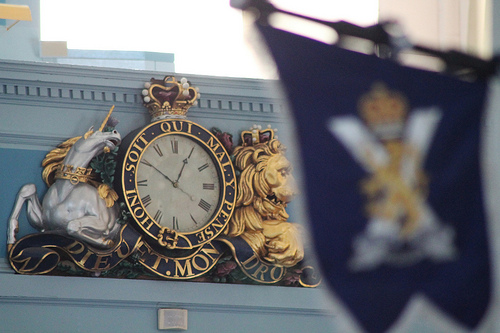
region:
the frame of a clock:
[115, 114, 238, 254]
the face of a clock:
[133, 127, 227, 234]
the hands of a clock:
[145, 155, 199, 209]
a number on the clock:
[168, 135, 183, 157]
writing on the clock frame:
[156, 115, 197, 141]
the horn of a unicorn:
[93, 94, 117, 134]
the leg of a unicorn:
[2, 178, 49, 241]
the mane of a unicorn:
[36, 132, 85, 187]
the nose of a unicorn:
[108, 123, 125, 138]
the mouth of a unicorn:
[100, 134, 122, 147]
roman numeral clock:
[8, 75, 300, 293]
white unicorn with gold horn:
[7, 102, 122, 301]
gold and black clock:
[118, 115, 241, 280]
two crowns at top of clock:
[135, 65, 200, 117]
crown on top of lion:
[235, 111, 312, 266]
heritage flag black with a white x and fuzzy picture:
[243, 0, 484, 328]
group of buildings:
[0, 0, 175, 65]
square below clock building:
[150, 305, 191, 330]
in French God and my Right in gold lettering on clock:
[58, 233, 350, 299]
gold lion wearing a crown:
[233, 125, 295, 291]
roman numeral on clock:
[169, 218, 188, 237]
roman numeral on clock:
[151, 210, 168, 225]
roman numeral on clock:
[138, 193, 153, 208]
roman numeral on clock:
[140, 177, 150, 195]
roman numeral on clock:
[135, 154, 157, 170]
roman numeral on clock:
[149, 141, 165, 163]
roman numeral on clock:
[166, 136, 183, 157]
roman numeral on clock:
[185, 143, 197, 161]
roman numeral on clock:
[193, 162, 213, 177]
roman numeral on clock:
[202, 182, 219, 192]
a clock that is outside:
[22, 25, 322, 324]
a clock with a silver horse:
[22, 52, 435, 331]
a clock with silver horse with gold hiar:
[37, 55, 377, 324]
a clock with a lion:
[62, 14, 384, 330]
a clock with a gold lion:
[27, 42, 407, 330]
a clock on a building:
[27, 27, 346, 323]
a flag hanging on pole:
[208, 2, 498, 282]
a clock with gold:
[55, 32, 303, 332]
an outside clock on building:
[32, 25, 377, 306]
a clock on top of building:
[97, 39, 375, 320]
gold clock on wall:
[25, 71, 310, 287]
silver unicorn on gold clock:
[28, 99, 121, 269]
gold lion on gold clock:
[230, 126, 305, 285]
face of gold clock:
[128, 129, 245, 262]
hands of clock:
[141, 144, 205, 198]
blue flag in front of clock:
[245, 31, 499, 313]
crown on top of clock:
[140, 69, 212, 123]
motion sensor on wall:
[150, 304, 205, 330]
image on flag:
[317, 83, 465, 271]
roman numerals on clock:
[195, 164, 227, 202]